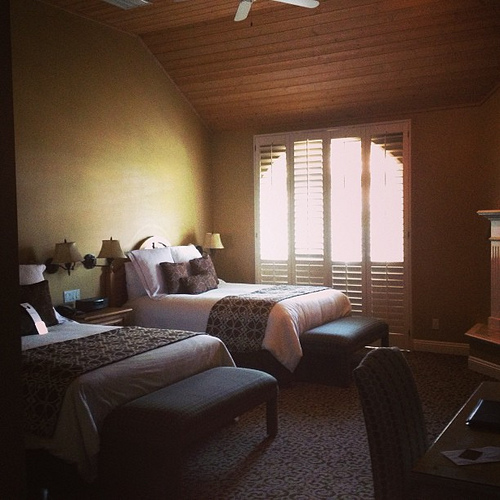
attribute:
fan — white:
[234, 0, 322, 23]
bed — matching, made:
[104, 234, 353, 374]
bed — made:
[18, 263, 240, 483]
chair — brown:
[351, 346, 431, 500]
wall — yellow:
[11, 0, 215, 310]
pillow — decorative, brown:
[159, 260, 191, 296]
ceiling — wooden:
[44, 0, 498, 139]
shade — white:
[251, 118, 415, 352]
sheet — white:
[123, 282, 355, 373]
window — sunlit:
[258, 137, 410, 267]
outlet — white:
[431, 318, 441, 331]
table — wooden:
[55, 303, 133, 328]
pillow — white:
[127, 246, 174, 299]